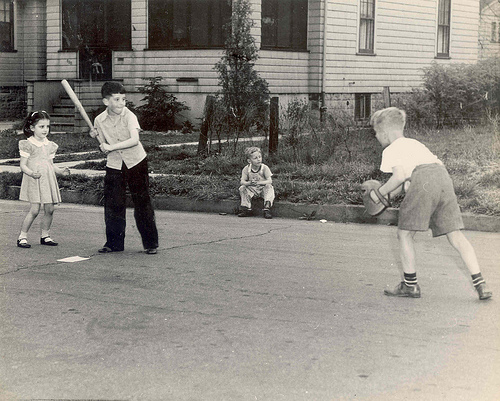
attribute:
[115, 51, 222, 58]
white siding — brick, vintage, old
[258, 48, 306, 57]
siding — white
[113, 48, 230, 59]
siding — white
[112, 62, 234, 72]
siding — white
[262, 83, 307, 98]
siding — white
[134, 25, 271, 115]
siding — white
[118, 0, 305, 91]
siding — white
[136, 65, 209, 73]
siding — white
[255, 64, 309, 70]
siding — white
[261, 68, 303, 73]
siding — white